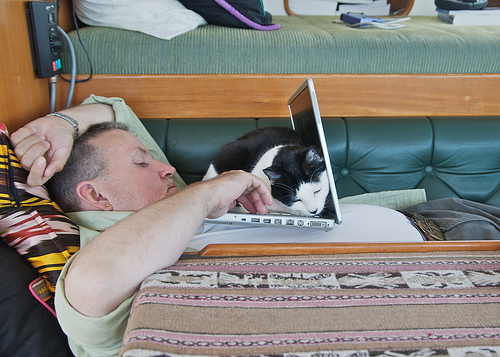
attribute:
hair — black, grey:
[42, 119, 131, 214]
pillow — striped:
[2, 120, 51, 266]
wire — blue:
[45, 14, 85, 100]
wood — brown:
[0, 1, 498, 257]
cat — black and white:
[172, 90, 352, 250]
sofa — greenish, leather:
[130, 114, 496, 229]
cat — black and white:
[216, 128, 332, 211]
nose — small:
[305, 197, 323, 217]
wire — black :
[54, 0, 94, 85]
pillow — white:
[71, 0, 206, 47]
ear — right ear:
[259, 162, 280, 183]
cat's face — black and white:
[261, 147, 330, 216]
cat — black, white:
[203, 124, 330, 214]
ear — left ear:
[306, 141, 316, 161]